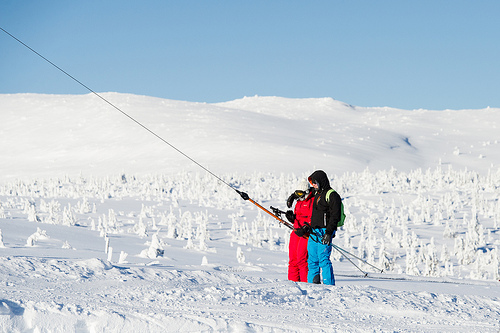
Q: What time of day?
A: Daytime.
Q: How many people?
A: Two.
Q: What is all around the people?
A: Snow.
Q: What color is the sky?
A: Blue.